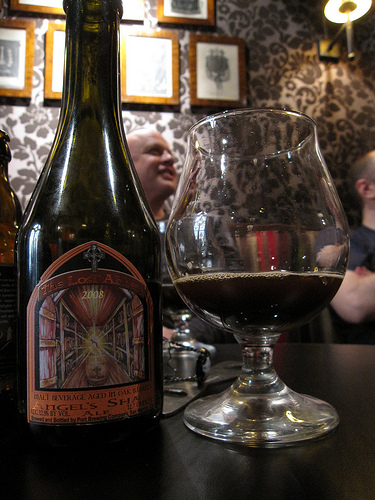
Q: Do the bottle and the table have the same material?
A: No, the bottle is made of glass and the table is made of wood.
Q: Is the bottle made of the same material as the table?
A: No, the bottle is made of glass and the table is made of wood.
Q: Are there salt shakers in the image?
A: No, there are no salt shakers.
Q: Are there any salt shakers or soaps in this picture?
A: No, there are no salt shakers or soaps.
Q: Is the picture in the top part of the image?
A: Yes, the picture is in the top of the image.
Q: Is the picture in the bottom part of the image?
A: No, the picture is in the top of the image.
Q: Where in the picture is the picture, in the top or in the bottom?
A: The picture is in the top of the image.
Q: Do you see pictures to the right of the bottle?
A: Yes, there is a picture to the right of the bottle.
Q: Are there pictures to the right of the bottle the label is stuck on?
A: Yes, there is a picture to the right of the bottle.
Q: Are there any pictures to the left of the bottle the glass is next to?
A: No, the picture is to the right of the bottle.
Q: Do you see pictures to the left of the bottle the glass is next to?
A: No, the picture is to the right of the bottle.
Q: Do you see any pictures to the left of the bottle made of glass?
A: No, the picture is to the right of the bottle.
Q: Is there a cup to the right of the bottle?
A: No, there is a picture to the right of the bottle.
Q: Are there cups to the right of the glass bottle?
A: No, there is a picture to the right of the bottle.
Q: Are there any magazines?
A: No, there are no magazines.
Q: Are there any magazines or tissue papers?
A: No, there are no magazines or tissue papers.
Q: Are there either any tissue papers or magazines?
A: No, there are no magazines or tissue papers.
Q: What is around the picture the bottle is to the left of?
A: The frame is around the picture.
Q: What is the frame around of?
A: The frame is around the picture.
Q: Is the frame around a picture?
A: Yes, the frame is around a picture.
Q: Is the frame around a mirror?
A: No, the frame is around a picture.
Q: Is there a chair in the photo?
A: Yes, there is a chair.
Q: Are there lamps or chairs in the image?
A: Yes, there is a chair.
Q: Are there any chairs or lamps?
A: Yes, there is a chair.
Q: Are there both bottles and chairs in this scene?
A: Yes, there are both a chair and a bottle.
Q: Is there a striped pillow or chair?
A: Yes, there is a striped chair.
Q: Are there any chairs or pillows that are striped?
A: Yes, the chair is striped.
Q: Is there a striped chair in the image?
A: Yes, there is a striped chair.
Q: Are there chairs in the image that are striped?
A: Yes, there is a chair that is striped.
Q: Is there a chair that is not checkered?
A: Yes, there is a striped chair.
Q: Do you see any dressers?
A: No, there are no dressers.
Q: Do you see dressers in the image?
A: No, there are no dressers.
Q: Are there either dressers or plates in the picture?
A: No, there are no dressers or plates.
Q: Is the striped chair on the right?
A: Yes, the chair is on the right of the image.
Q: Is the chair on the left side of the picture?
A: No, the chair is on the right of the image.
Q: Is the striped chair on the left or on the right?
A: The chair is on the right of the image.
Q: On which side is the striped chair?
A: The chair is on the right of the image.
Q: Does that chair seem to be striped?
A: Yes, the chair is striped.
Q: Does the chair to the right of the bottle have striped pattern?
A: Yes, the chair is striped.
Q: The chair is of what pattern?
A: The chair is striped.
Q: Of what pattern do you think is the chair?
A: The chair is striped.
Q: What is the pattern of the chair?
A: The chair is striped.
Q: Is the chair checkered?
A: No, the chair is striped.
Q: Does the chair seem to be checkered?
A: No, the chair is striped.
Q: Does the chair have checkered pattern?
A: No, the chair is striped.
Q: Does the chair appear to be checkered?
A: No, the chair is striped.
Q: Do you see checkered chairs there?
A: No, there is a chair but it is striped.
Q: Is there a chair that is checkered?
A: No, there is a chair but it is striped.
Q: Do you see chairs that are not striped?
A: No, there is a chair but it is striped.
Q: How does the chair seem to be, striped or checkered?
A: The chair is striped.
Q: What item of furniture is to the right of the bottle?
A: The piece of furniture is a chair.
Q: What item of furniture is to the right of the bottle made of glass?
A: The piece of furniture is a chair.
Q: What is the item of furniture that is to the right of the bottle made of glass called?
A: The piece of furniture is a chair.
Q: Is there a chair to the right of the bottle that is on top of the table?
A: Yes, there is a chair to the right of the bottle.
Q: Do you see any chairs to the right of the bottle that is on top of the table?
A: Yes, there is a chair to the right of the bottle.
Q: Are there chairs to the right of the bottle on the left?
A: Yes, there is a chair to the right of the bottle.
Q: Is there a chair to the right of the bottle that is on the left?
A: Yes, there is a chair to the right of the bottle.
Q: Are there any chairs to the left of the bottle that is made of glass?
A: No, the chair is to the right of the bottle.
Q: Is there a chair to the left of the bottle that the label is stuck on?
A: No, the chair is to the right of the bottle.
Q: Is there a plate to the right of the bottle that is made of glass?
A: No, there is a chair to the right of the bottle.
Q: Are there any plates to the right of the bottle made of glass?
A: No, there is a chair to the right of the bottle.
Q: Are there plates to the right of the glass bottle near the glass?
A: No, there is a chair to the right of the bottle.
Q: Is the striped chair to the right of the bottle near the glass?
A: Yes, the chair is to the right of the bottle.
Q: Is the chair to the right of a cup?
A: No, the chair is to the right of the bottle.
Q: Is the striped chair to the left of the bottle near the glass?
A: No, the chair is to the right of the bottle.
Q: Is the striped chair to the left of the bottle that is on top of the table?
A: No, the chair is to the right of the bottle.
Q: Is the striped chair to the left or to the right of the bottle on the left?
A: The chair is to the right of the bottle.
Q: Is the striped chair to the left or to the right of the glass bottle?
A: The chair is to the right of the bottle.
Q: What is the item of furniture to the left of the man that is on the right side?
A: The piece of furniture is a chair.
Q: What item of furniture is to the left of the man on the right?
A: The piece of furniture is a chair.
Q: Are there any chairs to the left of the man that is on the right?
A: Yes, there is a chair to the left of the man.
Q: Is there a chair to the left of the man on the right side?
A: Yes, there is a chair to the left of the man.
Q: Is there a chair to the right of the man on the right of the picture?
A: No, the chair is to the left of the man.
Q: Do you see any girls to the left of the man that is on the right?
A: No, there is a chair to the left of the man.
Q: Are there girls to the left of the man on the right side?
A: No, there is a chair to the left of the man.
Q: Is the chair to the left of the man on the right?
A: Yes, the chair is to the left of the man.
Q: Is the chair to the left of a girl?
A: No, the chair is to the left of the man.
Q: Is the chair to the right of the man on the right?
A: No, the chair is to the left of the man.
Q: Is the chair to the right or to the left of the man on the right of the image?
A: The chair is to the left of the man.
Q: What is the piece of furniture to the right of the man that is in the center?
A: The piece of furniture is a chair.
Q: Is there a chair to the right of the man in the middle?
A: Yes, there is a chair to the right of the man.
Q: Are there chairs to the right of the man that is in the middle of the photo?
A: Yes, there is a chair to the right of the man.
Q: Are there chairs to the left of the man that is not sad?
A: No, the chair is to the right of the man.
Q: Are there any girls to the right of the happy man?
A: No, there is a chair to the right of the man.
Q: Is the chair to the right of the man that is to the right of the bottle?
A: Yes, the chair is to the right of the man.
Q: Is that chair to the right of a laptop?
A: No, the chair is to the right of the man.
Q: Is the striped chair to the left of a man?
A: No, the chair is to the right of a man.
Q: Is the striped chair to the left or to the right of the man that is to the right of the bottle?
A: The chair is to the right of the man.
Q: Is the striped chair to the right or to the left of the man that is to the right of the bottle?
A: The chair is to the right of the man.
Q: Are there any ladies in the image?
A: No, there are no ladies.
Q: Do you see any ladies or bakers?
A: No, there are no ladies or bakers.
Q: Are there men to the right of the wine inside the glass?
A: Yes, there is a man to the right of the wine.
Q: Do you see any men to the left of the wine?
A: No, the man is to the right of the wine.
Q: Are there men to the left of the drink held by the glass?
A: No, the man is to the right of the wine.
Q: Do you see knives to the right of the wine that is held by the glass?
A: No, there is a man to the right of the wine.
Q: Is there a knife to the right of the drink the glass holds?
A: No, there is a man to the right of the wine.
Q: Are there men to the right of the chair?
A: Yes, there is a man to the right of the chair.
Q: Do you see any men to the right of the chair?
A: Yes, there is a man to the right of the chair.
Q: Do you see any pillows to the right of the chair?
A: No, there is a man to the right of the chair.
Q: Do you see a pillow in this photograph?
A: No, there are no pillows.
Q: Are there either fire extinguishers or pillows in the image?
A: No, there are no pillows or fire extinguishers.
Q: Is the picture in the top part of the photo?
A: Yes, the picture is in the top of the image.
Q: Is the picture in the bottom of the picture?
A: No, the picture is in the top of the image.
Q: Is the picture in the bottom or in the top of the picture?
A: The picture is in the top of the image.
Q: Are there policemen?
A: No, there are no policemen.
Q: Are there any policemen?
A: No, there are no policemen.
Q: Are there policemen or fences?
A: No, there are no policemen or fences.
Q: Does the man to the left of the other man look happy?
A: Yes, the man is happy.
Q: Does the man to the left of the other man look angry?
A: No, the man is happy.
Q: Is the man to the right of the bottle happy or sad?
A: The man is happy.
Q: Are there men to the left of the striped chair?
A: Yes, there is a man to the left of the chair.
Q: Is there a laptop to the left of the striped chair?
A: No, there is a man to the left of the chair.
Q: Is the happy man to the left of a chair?
A: Yes, the man is to the left of a chair.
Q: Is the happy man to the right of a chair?
A: No, the man is to the left of a chair.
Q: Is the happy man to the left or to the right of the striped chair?
A: The man is to the left of the chair.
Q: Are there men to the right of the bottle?
A: Yes, there is a man to the right of the bottle.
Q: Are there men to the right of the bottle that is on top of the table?
A: Yes, there is a man to the right of the bottle.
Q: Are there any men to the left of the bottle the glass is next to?
A: No, the man is to the right of the bottle.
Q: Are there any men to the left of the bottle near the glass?
A: No, the man is to the right of the bottle.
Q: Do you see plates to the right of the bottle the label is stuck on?
A: No, there is a man to the right of the bottle.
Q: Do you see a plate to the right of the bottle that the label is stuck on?
A: No, there is a man to the right of the bottle.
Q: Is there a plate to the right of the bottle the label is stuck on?
A: No, there is a man to the right of the bottle.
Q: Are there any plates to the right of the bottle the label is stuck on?
A: No, there is a man to the right of the bottle.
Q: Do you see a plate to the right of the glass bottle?
A: No, there is a man to the right of the bottle.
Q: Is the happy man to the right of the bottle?
A: Yes, the man is to the right of the bottle.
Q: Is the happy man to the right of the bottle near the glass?
A: Yes, the man is to the right of the bottle.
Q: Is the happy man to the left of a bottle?
A: No, the man is to the right of a bottle.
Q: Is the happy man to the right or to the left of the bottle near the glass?
A: The man is to the right of the bottle.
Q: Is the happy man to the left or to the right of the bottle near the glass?
A: The man is to the right of the bottle.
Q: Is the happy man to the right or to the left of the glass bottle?
A: The man is to the right of the bottle.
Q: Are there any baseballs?
A: No, there are no baseballs.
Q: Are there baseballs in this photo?
A: No, there are no baseballs.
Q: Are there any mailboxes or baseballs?
A: No, there are no baseballs or mailboxes.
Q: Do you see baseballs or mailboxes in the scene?
A: No, there are no baseballs or mailboxes.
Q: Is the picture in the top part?
A: Yes, the picture is in the top of the image.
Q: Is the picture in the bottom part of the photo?
A: No, the picture is in the top of the image.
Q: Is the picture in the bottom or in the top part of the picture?
A: The picture is in the top of the image.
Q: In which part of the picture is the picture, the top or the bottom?
A: The picture is in the top of the image.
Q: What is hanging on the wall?
A: The picture is hanging on the wall.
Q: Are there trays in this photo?
A: No, there are no trays.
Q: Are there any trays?
A: No, there are no trays.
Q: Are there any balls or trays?
A: No, there are no trays or balls.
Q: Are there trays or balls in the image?
A: No, there are no trays or balls.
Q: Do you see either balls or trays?
A: No, there are no trays or balls.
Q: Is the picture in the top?
A: Yes, the picture is in the top of the image.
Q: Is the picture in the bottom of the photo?
A: No, the picture is in the top of the image.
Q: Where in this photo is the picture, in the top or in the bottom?
A: The picture is in the top of the image.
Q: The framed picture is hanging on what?
A: The picture is hanging on the wall.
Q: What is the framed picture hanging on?
A: The picture is hanging on the wall.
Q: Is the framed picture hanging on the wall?
A: Yes, the picture is hanging on the wall.